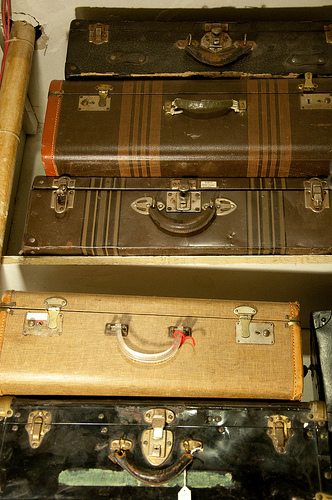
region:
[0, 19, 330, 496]
A group of suitcases.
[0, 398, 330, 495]
The metal suitcase is black.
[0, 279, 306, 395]
A tan colored suitcase.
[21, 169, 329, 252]
A brown suitcase with light brown stripes.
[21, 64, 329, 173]
A brown suitcase with orange on the side.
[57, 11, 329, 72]
The suitcase is dark brown.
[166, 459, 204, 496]
A tag on the suitcase.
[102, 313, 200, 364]
A clear handle on the suitcase.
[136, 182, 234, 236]
A brown handle on the suitcase.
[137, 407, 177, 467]
A metal clasp on the suitcase.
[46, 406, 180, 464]
brown and tan luggage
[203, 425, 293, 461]
brown and tan luggage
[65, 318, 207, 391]
brown and tan luggage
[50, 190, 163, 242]
old brown and tan luggage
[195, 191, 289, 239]
old brown and tan luggage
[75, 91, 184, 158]
old brown and tan luggage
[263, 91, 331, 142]
old brown and tan luggage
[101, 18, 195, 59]
old brown and tan luggage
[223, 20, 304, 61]
old brown and tan luggage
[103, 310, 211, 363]
old brown and tan luggage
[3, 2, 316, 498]
five oldsuit cases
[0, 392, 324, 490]
black metal suit case with tag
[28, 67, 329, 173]
old brown and orange suit case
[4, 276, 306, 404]
gold suit case with red ribbon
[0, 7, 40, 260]
pipe coming out of wall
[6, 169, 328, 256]
old brown striped suit case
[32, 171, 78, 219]
open suit case latch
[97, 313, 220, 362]
clear suit case handle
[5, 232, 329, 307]
wall dividing suit cases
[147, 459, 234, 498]
white tag on suitcase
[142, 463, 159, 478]
edge of a handle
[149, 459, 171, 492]
part of a gandle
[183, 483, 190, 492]
edge of a tag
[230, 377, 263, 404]
edge of a scroll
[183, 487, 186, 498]
the tag is white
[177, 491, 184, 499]
the tag is white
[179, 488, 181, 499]
the tag is white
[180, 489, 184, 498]
the tag is white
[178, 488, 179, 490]
the tag is white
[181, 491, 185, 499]
the tag is white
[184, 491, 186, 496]
the tag is white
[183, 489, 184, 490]
the tag is white